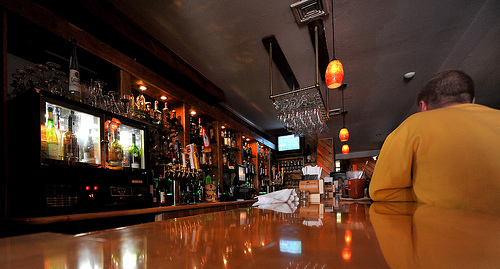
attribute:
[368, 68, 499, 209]
man — customer, sitting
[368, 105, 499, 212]
shirt — yellow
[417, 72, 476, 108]
hair — short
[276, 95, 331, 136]
glasses — upside down, hung, hanging, stemmed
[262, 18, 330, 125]
rack — hanging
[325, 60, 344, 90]
light — small, hung, orange, yellow, on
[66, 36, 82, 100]
bottle — tall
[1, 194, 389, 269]
bar — reflecting, organized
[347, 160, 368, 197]
drink — red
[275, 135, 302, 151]
tv — far, lit, small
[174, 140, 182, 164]
tap — black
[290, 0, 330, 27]
vent — high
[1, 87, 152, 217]
refrigerator — lighted, black, cool, on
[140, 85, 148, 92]
light — round